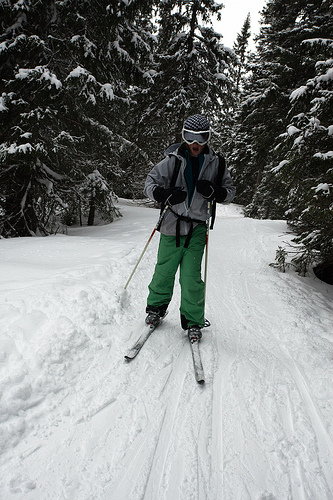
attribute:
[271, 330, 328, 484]
lines — white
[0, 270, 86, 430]
mound — small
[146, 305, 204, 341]
feet — black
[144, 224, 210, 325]
pants — green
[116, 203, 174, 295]
pole — silver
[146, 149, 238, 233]
jacket — gray, black, grey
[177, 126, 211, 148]
goggles — silver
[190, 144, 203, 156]
mouth — open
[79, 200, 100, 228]
base — small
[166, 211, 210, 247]
strap — black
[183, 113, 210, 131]
hat — black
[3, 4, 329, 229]
trees — green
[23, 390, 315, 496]
snow — white, soft